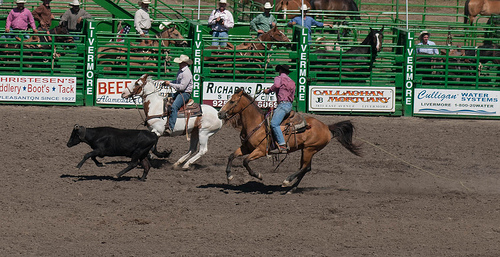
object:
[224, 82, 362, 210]
horse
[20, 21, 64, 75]
horse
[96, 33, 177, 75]
horse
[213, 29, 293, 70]
horse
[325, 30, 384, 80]
horse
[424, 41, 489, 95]
horse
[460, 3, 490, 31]
horse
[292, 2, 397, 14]
horse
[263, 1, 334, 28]
horse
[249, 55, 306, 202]
man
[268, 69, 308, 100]
shirt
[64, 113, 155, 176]
cow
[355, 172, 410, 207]
dirt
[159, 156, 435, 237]
ground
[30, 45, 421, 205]
stable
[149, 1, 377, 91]
fence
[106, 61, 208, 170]
horse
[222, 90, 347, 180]
horse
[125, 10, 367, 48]
men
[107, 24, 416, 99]
fence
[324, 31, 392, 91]
horse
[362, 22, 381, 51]
stripe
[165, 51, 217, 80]
hat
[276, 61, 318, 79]
hat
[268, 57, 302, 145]
man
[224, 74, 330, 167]
horse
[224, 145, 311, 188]
legs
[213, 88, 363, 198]
horse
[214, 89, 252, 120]
head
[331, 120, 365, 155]
tail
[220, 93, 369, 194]
horse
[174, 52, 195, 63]
hat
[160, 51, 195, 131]
man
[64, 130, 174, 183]
animal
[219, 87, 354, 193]
horse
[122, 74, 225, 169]
horse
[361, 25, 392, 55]
horse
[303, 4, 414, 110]
gate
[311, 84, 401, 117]
advertisement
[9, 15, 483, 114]
wall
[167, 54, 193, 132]
man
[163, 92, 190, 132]
jeans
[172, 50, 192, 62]
cowboy hat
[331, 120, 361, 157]
tail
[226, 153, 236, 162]
knee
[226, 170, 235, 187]
hoof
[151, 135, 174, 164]
tail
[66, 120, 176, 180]
bull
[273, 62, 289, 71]
hat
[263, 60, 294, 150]
man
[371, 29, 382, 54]
face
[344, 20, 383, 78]
horse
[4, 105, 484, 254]
dirt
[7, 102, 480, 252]
field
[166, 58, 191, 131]
man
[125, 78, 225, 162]
horse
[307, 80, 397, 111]
advertisement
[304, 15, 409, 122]
wall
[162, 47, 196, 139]
horse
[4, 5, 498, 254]
picture